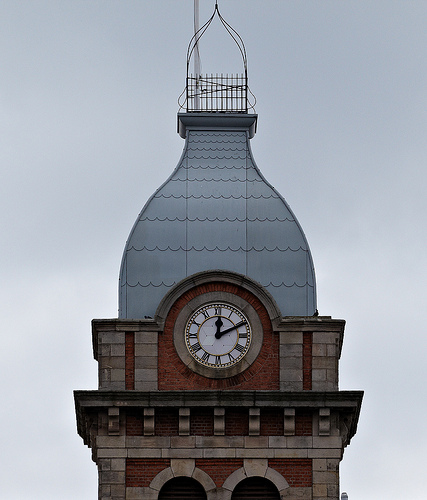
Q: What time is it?
A: 12:10.